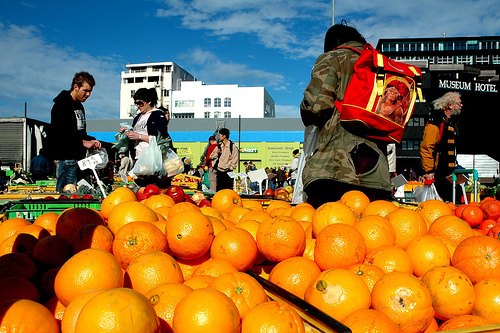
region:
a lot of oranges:
[32, 208, 487, 323]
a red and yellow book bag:
[346, 40, 417, 145]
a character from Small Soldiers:
[378, 80, 406, 124]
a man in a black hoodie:
[44, 70, 104, 170]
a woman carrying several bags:
[110, 77, 188, 177]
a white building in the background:
[119, 50, 279, 120]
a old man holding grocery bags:
[411, 87, 481, 204]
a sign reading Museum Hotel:
[434, 68, 499, 98]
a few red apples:
[129, 178, 219, 211]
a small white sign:
[70, 150, 115, 202]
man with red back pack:
[296, 15, 460, 207]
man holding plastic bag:
[382, 80, 469, 218]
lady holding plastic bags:
[105, 65, 189, 205]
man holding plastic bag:
[47, 67, 132, 183]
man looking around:
[190, 107, 244, 207]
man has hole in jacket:
[277, 55, 437, 220]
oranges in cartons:
[26, 167, 461, 332]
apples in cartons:
[120, 174, 244, 221]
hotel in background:
[372, 37, 498, 192]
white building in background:
[115, 38, 297, 155]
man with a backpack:
[293, 24, 418, 200]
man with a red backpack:
[302, 16, 420, 202]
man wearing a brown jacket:
[288, 20, 423, 202]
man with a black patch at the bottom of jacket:
[288, 23, 433, 200]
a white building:
[118, 53, 274, 120]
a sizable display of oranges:
[12, 192, 492, 331]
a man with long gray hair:
[414, 89, 471, 201]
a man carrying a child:
[188, 125, 235, 199]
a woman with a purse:
[117, 84, 193, 201]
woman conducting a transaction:
[112, 89, 183, 190]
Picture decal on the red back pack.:
[379, 77, 410, 115]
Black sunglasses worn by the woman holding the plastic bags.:
[132, 92, 152, 105]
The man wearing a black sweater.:
[55, 88, 97, 126]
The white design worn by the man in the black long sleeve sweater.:
[72, 104, 90, 134]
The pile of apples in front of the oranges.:
[132, 183, 201, 204]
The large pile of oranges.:
[3, 196, 499, 331]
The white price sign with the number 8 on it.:
[67, 156, 117, 198]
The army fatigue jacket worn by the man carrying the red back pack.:
[313, 51, 388, 181]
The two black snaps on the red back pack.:
[376, 63, 426, 88]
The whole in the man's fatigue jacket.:
[346, 136, 383, 178]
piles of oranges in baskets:
[105, 193, 410, 289]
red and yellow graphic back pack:
[342, 45, 439, 160]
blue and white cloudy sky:
[64, 30, 309, 58]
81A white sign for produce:
[64, 154, 137, 212]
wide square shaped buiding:
[137, 57, 279, 113]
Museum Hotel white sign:
[440, 77, 497, 96]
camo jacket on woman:
[305, 50, 411, 198]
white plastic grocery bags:
[118, 138, 192, 182]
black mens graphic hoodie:
[58, 94, 102, 162]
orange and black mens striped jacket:
[417, 104, 474, 184]